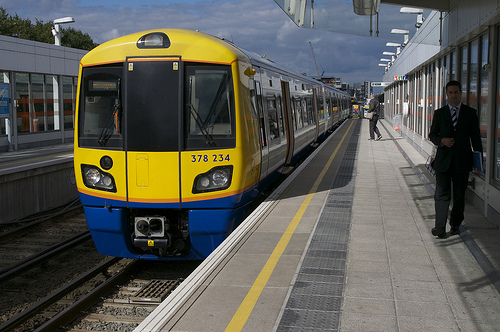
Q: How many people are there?
A: 2.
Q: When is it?
A: Day time.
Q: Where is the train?
A: On the track.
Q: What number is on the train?
A: 378 234.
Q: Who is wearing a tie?
A: The man.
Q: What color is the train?
A: Blue and yellow.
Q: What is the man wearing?
A: A suit.